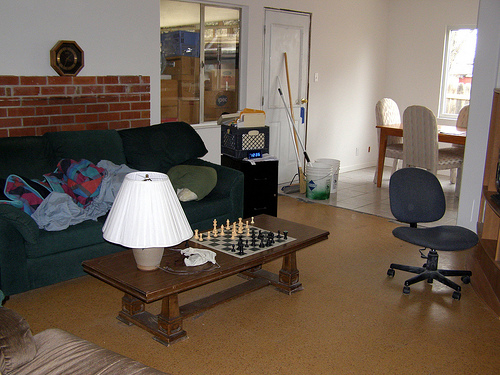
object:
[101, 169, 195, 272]
lamp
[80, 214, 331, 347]
table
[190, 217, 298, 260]
game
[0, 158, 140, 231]
clothes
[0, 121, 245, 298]
sofa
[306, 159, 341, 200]
buckets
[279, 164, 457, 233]
floor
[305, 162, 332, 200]
buckets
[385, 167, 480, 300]
chair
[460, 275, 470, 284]
wheels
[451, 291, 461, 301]
wheels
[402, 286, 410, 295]
wheels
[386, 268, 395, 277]
wheels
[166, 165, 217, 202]
pillow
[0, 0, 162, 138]
wall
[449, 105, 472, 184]
chair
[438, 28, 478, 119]
window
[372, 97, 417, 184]
chair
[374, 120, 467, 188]
table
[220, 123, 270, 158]
crate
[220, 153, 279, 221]
cabinet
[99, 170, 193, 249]
shade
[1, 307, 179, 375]
couch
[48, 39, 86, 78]
clock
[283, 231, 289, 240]
pieces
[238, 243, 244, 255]
pieces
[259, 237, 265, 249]
pieces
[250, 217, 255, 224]
pieces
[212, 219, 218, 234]
pieces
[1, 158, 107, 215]
quilt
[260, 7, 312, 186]
door